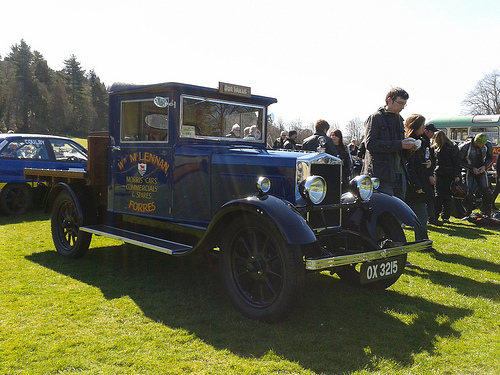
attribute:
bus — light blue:
[424, 116, 497, 144]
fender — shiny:
[186, 195, 318, 249]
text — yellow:
[117, 150, 170, 212]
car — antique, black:
[21, 80, 433, 323]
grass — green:
[33, 114, 490, 363]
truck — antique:
[116, 72, 384, 281]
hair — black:
[386, 85, 409, 102]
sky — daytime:
[0, 3, 491, 88]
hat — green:
[469, 126, 497, 152]